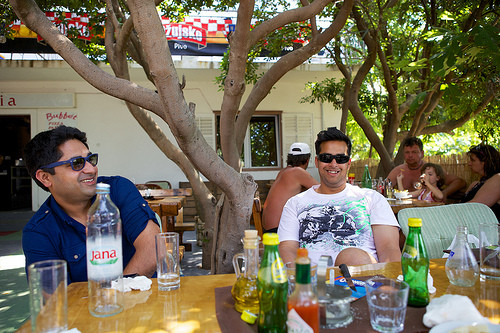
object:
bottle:
[85, 183, 127, 319]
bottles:
[444, 225, 481, 287]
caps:
[263, 232, 281, 246]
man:
[22, 125, 169, 295]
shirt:
[19, 173, 171, 298]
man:
[277, 127, 409, 285]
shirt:
[275, 181, 403, 276]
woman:
[461, 144, 500, 208]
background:
[0, 2, 489, 254]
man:
[261, 141, 318, 235]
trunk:
[200, 157, 253, 275]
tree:
[10, 0, 360, 269]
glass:
[28, 165, 69, 250]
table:
[15, 257, 500, 333]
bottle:
[285, 247, 320, 333]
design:
[298, 195, 376, 251]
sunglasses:
[39, 153, 99, 172]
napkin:
[424, 292, 495, 332]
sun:
[162, 320, 199, 332]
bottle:
[229, 227, 266, 316]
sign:
[1, 8, 319, 57]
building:
[0, 9, 361, 212]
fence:
[349, 152, 500, 190]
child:
[395, 163, 444, 205]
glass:
[372, 179, 377, 190]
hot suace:
[287, 300, 317, 333]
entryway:
[0, 111, 30, 214]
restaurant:
[1, 46, 381, 214]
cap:
[288, 142, 312, 155]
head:
[287, 143, 311, 170]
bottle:
[397, 217, 431, 307]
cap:
[407, 217, 423, 227]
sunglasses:
[317, 153, 351, 164]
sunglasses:
[469, 144, 493, 169]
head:
[467, 144, 498, 176]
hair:
[20, 125, 91, 192]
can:
[413, 173, 429, 190]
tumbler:
[364, 276, 412, 332]